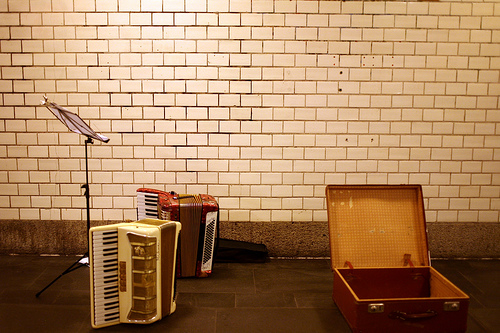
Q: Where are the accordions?
A: The stage.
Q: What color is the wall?
A: White.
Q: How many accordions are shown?
A: Two.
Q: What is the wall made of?
A: Brick.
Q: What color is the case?
A: Brown.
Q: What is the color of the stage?
A: Brown.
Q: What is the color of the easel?
A: Black.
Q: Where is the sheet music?
A: On easel.